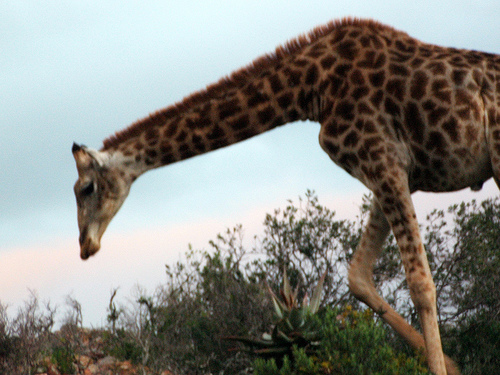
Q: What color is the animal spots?
A: Brown.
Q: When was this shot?
A: Daytime.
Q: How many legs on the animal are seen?
A: 2.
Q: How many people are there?
A: 0.